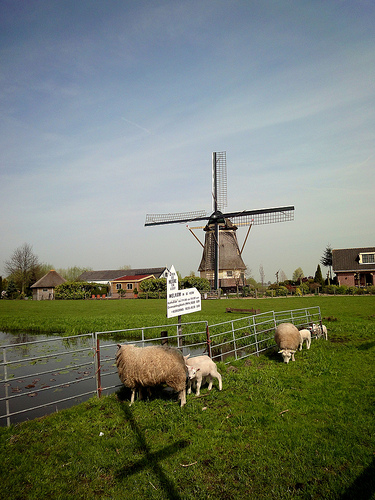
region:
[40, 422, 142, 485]
this is a grass area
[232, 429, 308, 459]
the grass is green in color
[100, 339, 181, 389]
this is a sheep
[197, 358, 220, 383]
this is the lamp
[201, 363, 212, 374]
the lamp is white in color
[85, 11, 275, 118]
this is the sky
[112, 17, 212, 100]
the sky is blue in color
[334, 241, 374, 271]
this is a building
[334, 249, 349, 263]
this is the roof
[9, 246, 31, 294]
this is a tree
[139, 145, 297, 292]
Wind mill in the background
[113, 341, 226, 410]
Adult sheep with two lambs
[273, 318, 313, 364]
Adult sheep with one lamb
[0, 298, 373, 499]
Field of green grass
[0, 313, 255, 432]
Pond beside a green field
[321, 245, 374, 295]
House surround by bushes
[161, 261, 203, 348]
Sign stuck in the pond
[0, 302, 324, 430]
Metal fence beside a pond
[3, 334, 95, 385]
Lily pads on a pond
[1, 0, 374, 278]
Sky partly covered with clouds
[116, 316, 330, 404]
a sheep eating grass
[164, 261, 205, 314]
instruction board white color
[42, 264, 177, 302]
building behind the lake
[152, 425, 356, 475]
a green grass near the pond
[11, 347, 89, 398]
a steel fencing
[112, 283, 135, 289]
window of the building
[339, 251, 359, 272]
roof of the building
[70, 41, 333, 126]
a blue colors sky in the white clouds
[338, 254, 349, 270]
roof of the building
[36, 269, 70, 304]
hut in the garden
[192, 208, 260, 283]
this is a maize mill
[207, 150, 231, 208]
this is a mill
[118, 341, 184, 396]
this is a ram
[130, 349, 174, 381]
the ram is wooly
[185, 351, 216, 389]
this is a kid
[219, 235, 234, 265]
the roof is brown in color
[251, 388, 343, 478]
the grass is long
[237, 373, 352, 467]
the grass is green in color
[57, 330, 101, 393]
this is a fence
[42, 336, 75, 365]
this is water beside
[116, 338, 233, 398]
the sheep on the grass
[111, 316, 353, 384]
the sheep beside the fence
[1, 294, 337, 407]
the fence is metal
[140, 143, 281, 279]
the large windmill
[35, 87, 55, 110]
the clear blue sky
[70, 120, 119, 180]
clouds in the sky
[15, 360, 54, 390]
leaves in the water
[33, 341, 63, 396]
the water is calm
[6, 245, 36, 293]
the tree without leaves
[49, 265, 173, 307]
the houses in the distance